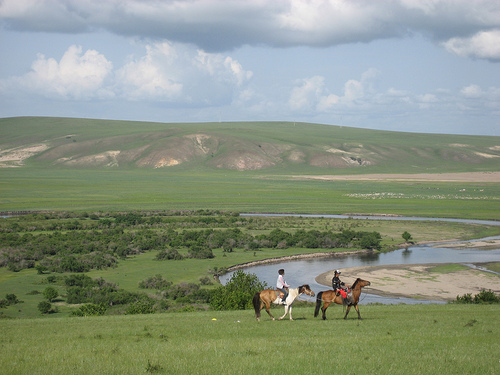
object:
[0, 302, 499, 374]
grass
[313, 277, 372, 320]
horse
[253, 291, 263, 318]
tail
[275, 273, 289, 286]
shirt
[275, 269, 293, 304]
man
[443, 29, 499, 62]
clouds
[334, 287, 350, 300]
pants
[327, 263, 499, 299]
ground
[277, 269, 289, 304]
woman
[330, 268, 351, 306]
man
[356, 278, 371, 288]
head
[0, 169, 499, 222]
field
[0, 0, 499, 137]
sky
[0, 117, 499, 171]
mountain range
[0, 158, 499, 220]
area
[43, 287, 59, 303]
trees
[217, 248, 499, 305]
river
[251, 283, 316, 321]
horse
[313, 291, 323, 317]
tail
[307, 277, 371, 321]
horse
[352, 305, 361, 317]
legs